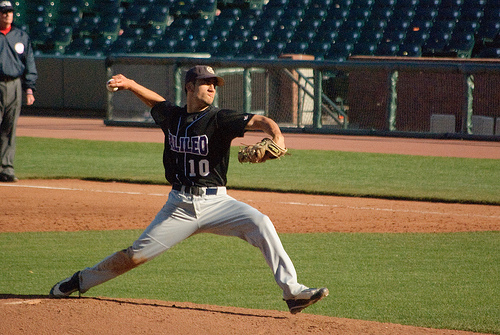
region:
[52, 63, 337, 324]
Baseball player throwing baseball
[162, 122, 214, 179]
Player's jersey with GALILEO 10 printed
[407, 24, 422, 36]
Orange sticker on stadium seat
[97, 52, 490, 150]
Green padding on dugout railing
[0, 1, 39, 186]
Umpire standing by first base line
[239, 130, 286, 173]
Brown baseball glove on player's left hand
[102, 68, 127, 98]
Baseball in player's right hand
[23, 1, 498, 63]
Blue stadium seats on first base side of field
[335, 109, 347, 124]
Orange light inside dugout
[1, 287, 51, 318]
White pitcher's rubber on mound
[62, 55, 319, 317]
This man is playing baseball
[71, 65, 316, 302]
This is a pitcher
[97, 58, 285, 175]
Pitcher is throwing baseball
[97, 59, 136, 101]
This is a baseball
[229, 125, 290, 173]
This is a mitt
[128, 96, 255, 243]
Uniform is black and grey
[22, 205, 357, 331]
Pitcher's legs are spread apart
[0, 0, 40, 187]
Man is standing in background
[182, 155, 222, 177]
Number 10 on uniform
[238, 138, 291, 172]
the pitchers glove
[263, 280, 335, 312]
the baseball players cleat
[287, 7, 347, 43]
empty seats in the stands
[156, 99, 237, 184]
the players team logo and number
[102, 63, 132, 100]
the players hand about to release the ball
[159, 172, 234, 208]
the baseball players belt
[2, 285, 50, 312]
the pitchers mound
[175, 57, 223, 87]
the baseball players hat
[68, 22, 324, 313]
baseball player is about to release to ball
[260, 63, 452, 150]
the dugout is empty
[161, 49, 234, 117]
the head of a man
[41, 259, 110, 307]
the foot of a man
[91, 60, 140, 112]
the hand of a man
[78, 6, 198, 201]
the arm of a man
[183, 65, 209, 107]
the ear of a man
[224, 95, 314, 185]
a man wearing a glove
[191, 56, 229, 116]
the eyes of a man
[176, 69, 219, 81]
man has black cap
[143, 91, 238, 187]
black and purple shirt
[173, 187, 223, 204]
man has black belt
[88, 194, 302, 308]
man has grey pants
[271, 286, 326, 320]
man has black shoes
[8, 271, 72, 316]
man on pitcher's mound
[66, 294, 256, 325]
dirt around man is brown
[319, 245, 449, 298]
green grass on infield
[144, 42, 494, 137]
green fence behind man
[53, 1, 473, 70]
green and empty stands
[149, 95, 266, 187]
black baseball jersey with number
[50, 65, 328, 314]
the man throwing a baseball ball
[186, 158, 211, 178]
the number 10 on the player's shirt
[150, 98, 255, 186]
the black shirt on the player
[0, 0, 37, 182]
a man in a dark blue jacket standing in the background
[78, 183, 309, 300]
the white pants the player is wearing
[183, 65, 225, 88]
the hat on the player's head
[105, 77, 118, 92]
the ball in the player's hand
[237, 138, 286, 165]
the glove on the player's left hand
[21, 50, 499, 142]
the fence around the baseball field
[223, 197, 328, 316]
the player's left leg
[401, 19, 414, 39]
a blue chair in the stadium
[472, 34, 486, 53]
a blue chair in the stadium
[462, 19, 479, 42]
a blue chair in the stadium